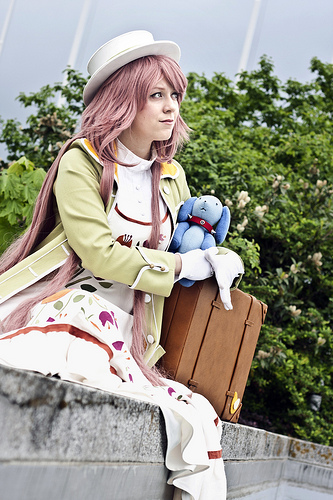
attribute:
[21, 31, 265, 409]
girl — looking, sitting, young, white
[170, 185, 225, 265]
dog — doll, stuffed, blue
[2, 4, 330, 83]
sky — clear, open, big, blue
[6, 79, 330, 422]
trees — green, wide, short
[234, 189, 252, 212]
flowers —  white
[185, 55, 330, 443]
bush —  green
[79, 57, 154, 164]
hair —  pink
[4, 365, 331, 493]
wall —  stone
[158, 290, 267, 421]
suitcase —  Brown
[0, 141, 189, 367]
coat —  Beige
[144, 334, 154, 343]
buttons —  white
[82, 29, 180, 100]
hat —  white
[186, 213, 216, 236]
collar —  Red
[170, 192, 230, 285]
animal —   Blue,  stuffed ,  blue,   stuffed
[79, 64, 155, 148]
hair —  Woman's,   long,  pink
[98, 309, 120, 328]
flowers —  pink 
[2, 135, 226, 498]
dress —  White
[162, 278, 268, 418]
suitcase —  Tan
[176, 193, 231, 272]
stuffed dog — blue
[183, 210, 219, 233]
collar — red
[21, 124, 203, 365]
jacket — green, white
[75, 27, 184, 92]
hat — white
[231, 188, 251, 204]
flowers — white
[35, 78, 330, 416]
bush — green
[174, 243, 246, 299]
gloves — white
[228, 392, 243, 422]
piece — little, yellow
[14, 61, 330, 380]
bushes — green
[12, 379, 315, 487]
wall — gray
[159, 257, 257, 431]
suitcase — brown